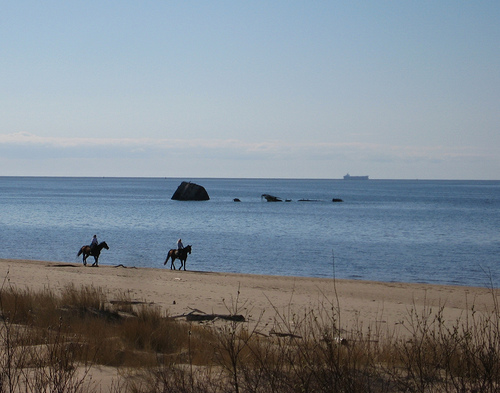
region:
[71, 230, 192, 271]
Two people horseback riding on the beach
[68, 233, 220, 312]
2 horses on the beache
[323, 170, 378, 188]
Ship off in the distance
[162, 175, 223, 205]
rock in the water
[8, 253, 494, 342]
Sand on the beach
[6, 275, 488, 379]
Tall weeds on the beach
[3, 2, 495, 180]
Hazy mostly clear blue sky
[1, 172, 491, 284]
Blue water under the sky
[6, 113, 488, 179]
Line of clouds in the sky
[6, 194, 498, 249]
Shallow area of the water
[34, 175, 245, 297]
two horsemen in front the ocean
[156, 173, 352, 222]
stones in middle of the ocean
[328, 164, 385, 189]
a ship in the ocean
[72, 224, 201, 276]
horses face to the right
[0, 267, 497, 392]
dry plants grow in the sand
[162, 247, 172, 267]
long tail of horse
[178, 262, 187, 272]
front legs of horse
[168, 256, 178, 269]
back legs of horse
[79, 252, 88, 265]
back legs of horse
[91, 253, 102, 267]
front legs of horse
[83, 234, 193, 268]
two people on horses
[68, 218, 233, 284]
two people riding horses on the beach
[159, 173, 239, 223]
rock out in the ocean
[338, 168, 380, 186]
ship out at sea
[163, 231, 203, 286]
person on a horse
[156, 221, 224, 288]
person on a horse on the beach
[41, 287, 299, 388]
weeds on the beach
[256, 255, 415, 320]
sand on the beach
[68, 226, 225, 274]
two horses on the sand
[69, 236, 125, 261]
dark horse walking on the beach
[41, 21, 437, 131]
The sky is the color blue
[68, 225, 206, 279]
Two people on their horses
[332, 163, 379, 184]
A ship on the water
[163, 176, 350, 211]
The items sticking out of the water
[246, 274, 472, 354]
The sand is the color brown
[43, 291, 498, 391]
The grass is the color brown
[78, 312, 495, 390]
The grass on the beach is dead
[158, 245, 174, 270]
The tail of the horse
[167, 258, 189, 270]
The legs of the horse